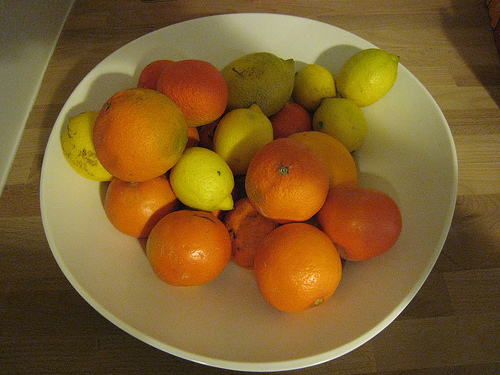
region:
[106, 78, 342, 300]
oranges on white plate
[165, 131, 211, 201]
lemons on white plate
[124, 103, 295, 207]
lemons in between oranges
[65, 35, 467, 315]
white plate on brown table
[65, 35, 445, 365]
plate is white and round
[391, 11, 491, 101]
table is brown wood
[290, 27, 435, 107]
lemon on edge of plate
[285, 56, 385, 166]
lemons smaller than oranges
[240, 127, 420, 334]
round oranges on round plate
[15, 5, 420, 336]
plate on table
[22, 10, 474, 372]
bowl of fruit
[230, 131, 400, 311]
group of oranges on the right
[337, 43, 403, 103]
one lemon on edge of plate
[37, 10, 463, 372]
white bowl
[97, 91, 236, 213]
one orange and one lemon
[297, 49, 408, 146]
three lemons on the right side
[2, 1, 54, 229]
white surface next to bowl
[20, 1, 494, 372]
wooden surface bowl is sitting on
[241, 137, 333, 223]
orange sitting on top of other oranges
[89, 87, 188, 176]
largest orange in the bowl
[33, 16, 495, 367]
white bowl on a wood floor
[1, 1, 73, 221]
white wall next to a wood floor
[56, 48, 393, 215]
seven lemons in a white bowl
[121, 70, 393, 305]
oranges in a white bowl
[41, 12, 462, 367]
large bowl of fruit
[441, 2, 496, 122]
shadow on wood floor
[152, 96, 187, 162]
green spot on an orange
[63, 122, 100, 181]
brown spots on a lemon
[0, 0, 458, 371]
white bowl next to a white wall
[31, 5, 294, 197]
rounded shadow case by bowl edge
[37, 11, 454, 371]
large white bowl of fruit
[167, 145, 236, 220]
yellow lemon with black spot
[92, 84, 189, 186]
navel orange with green spot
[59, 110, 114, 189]
brown spots on lemon rind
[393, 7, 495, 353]
light stained wooden table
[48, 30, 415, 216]
seven lemons in bowl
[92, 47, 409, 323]
twelve oranges in bowl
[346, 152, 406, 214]
shadow cast by orange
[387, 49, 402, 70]
green pointy tip of lemon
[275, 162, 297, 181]
brown stem of orange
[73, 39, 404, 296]
A pile of fruit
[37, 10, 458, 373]
A white ceramic plate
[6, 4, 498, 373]
A wooden table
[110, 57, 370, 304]
A pile of oranges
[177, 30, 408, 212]
A pile of lemons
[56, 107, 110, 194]
A lemon under an orange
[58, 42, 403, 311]
Oranges and lemons on a plate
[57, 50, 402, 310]
A pile of oranges and lemons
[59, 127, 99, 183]
some brown rot on a lemon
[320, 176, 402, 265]
an orange